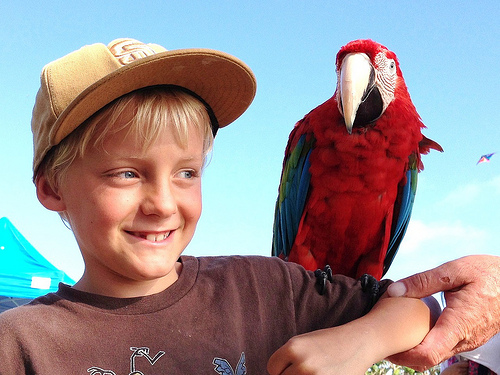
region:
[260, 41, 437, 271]
large parrot on shoulder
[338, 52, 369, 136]
white beak of parrot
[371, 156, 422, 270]
blue and green wing of parrot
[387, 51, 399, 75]
small black eye of parrot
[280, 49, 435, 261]
red feathers on parrot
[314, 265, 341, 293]
large talons of parrot feet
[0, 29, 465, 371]
parrot on kids shoulder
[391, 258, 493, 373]
hand holding kids arm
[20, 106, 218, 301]
young kid smiling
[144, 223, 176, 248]
two front teeth of kid's smile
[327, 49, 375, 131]
Parrot's white and black beak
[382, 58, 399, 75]
Parrot's left eye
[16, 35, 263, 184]
Boy's brown baseball cap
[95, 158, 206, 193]
Boy's blue eyes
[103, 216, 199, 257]
Boy's toothy smiling mouth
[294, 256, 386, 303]
Parrot's black sharp claws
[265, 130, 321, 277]
Parrot's blue and green right wing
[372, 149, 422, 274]
Parrot's blue and green left wing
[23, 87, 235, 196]
Boy's blond wavy hair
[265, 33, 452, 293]
Parrot sitting on boy's arm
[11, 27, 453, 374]
boy with parrot on his shoulder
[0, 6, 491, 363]
boy wearing tan baseball cap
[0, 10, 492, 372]
adult male hand holding boy's arm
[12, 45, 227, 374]
boy with blue eyes smiling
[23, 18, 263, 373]
boy with blonde hair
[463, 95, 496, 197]
red white and blue kite in sky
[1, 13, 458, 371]
red, green, and blue parrot looking at camera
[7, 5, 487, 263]
no clouds in sky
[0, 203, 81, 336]
tent with light green top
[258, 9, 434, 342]
bird's claws grasping boy's arm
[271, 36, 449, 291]
the colorful parrot standing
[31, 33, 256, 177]
the light colored hat on the boy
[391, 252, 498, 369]
the adult hand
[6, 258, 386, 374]
the brown short sleeved shirt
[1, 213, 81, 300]
the blue tent behind the boy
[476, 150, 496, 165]
the colorful kite in the sky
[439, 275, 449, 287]
the cut on the adults hand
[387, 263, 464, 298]
the thumb on the adult's hand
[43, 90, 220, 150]
the boy's blond hair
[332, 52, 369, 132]
the large beak on the bird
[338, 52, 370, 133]
The beak of the parrot.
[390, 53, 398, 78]
The eye of the parrot.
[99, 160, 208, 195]
The eyes of the boy.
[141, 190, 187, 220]
The nose of the boy.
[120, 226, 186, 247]
The mouth of the boy.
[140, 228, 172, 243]
The teeth of the boy.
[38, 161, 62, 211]
The left ear of the boy.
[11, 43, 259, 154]
The beige hat the boy is wearing.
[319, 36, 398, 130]
The head of the bird.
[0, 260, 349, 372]
The brown shirt of the boy.